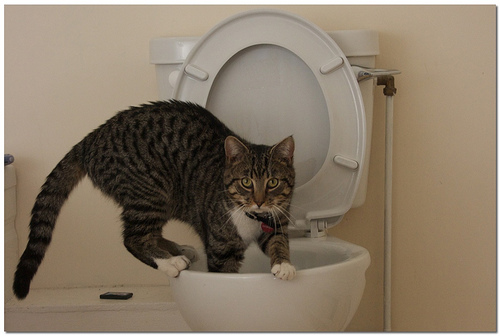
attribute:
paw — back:
[155, 249, 195, 277]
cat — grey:
[15, 65, 301, 301]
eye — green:
[263, 176, 279, 191]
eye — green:
[238, 177, 257, 194]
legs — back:
[95, 190, 227, 280]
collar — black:
[239, 201, 278, 226]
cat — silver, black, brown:
[10, 92, 307, 302]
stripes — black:
[122, 130, 197, 175]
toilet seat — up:
[174, 7, 369, 235]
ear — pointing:
[222, 135, 249, 162]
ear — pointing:
[267, 135, 294, 163]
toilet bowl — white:
[170, 232, 370, 332]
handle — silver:
[355, 67, 403, 82]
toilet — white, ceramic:
[148, 14, 376, 332]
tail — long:
[10, 137, 87, 300]